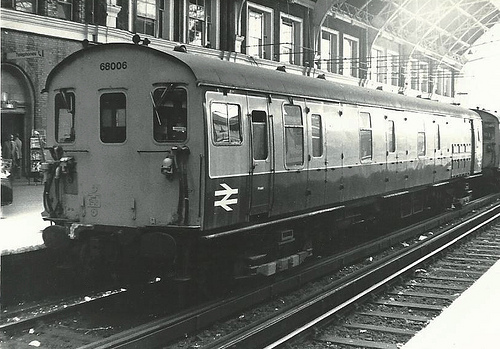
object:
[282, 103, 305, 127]
floor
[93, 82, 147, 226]
door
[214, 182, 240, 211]
symbol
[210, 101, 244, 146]
window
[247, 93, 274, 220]
door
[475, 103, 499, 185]
train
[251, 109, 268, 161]
side window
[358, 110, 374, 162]
side window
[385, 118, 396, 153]
side window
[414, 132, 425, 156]
side window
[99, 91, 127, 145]
window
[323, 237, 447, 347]
tracks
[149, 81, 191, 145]
window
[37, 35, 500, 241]
brown bear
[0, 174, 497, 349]
tracks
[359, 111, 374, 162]
window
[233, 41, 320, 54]
cable wires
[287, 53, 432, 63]
cable wires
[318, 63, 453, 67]
cable wires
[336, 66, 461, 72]
cable wires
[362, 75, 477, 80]
cable wires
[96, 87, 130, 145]
small window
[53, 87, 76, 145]
small window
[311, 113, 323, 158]
small window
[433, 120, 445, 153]
small window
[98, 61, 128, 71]
number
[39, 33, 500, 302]
rail car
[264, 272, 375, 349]
train track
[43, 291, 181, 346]
train track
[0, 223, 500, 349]
ground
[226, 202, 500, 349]
tracks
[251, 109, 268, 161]
window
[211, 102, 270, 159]
window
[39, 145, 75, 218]
pipes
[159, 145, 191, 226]
pipes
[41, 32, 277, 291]
train car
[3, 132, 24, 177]
people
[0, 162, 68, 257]
archway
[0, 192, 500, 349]
railroad tracks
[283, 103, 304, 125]
window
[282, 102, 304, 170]
window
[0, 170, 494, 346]
train tracks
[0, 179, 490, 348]
ground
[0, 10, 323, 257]
station